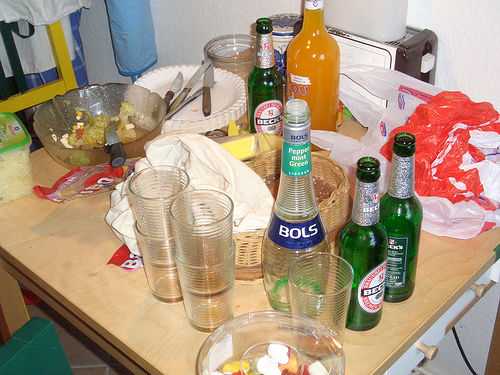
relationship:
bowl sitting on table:
[28, 78, 180, 173] [24, 46, 474, 365]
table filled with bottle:
[3, 75, 498, 373] [383, 128, 422, 302]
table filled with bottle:
[3, 75, 498, 373] [336, 155, 392, 334]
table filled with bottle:
[3, 75, 498, 373] [262, 95, 330, 312]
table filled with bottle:
[3, 75, 498, 373] [243, 15, 287, 138]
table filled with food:
[3, 75, 498, 373] [53, 99, 142, 164]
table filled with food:
[3, 75, 498, 373] [211, 338, 329, 373]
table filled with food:
[3, 75, 498, 373] [0, 111, 34, 205]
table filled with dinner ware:
[3, 75, 498, 373] [161, 57, 216, 117]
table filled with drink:
[3, 75, 498, 373] [284, 0, 343, 153]